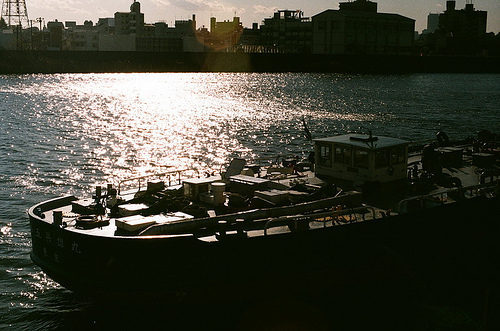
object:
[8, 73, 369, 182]
light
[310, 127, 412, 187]
room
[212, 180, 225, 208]
metal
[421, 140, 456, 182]
man sitting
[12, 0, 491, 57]
skyline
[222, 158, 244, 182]
open hatch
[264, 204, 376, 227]
railing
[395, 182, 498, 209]
railing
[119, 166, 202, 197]
railing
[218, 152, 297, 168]
railing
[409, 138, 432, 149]
railing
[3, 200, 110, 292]
writing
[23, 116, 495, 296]
ship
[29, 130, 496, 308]
ship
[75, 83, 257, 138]
sun reflecting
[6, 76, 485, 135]
water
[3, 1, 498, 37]
white clouds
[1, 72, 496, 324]
river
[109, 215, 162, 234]
hatch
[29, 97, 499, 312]
boat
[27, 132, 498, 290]
ship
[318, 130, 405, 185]
captain room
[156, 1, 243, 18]
clouds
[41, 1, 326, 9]
sky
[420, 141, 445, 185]
man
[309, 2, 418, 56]
building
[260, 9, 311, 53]
building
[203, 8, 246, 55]
building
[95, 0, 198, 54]
building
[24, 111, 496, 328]
ship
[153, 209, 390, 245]
edge